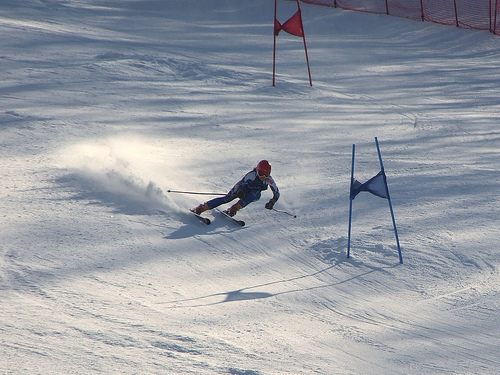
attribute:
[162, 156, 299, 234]
skiier — making turn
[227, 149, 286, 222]
skier — leaning into turn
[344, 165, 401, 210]
flag — blue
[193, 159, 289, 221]
man — skating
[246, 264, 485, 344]
prints — ski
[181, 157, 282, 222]
person — skiing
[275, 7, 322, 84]
flag — red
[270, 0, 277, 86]
pole — red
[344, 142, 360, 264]
pole — blue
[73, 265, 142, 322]
snow — splashing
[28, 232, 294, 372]
ice — view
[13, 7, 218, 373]
snow — flying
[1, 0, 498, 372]
ice — disturbed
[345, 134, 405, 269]
flag — course